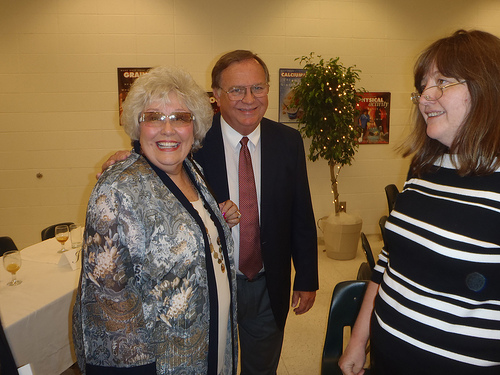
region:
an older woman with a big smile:
[82, 69, 249, 374]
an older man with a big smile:
[201, 46, 323, 373]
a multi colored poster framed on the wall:
[113, 62, 157, 127]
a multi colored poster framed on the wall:
[200, 90, 226, 119]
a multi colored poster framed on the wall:
[277, 69, 325, 124]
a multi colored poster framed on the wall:
[351, 88, 395, 142]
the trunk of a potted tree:
[327, 158, 342, 214]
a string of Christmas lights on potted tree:
[304, 53, 352, 213]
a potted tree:
[287, 51, 366, 256]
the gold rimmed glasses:
[408, 75, 468, 107]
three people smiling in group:
[108, 48, 470, 373]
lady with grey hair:
[121, 77, 192, 167]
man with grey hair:
[203, 52, 270, 135]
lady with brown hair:
[403, 37, 498, 166]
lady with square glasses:
[122, 83, 198, 172]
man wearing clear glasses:
[210, 46, 277, 126]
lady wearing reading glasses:
[414, 45, 476, 141]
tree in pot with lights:
[296, 65, 360, 257]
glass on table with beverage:
[0, 242, 32, 292]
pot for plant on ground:
[323, 203, 360, 255]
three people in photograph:
[38, 56, 485, 374]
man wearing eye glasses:
[216, 70, 283, 110]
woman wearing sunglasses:
[135, 88, 200, 152]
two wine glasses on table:
[1, 229, 109, 313]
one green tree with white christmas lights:
[294, 55, 384, 276]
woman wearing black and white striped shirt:
[402, 125, 498, 346]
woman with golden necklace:
[151, 190, 256, 287]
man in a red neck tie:
[221, 116, 314, 346]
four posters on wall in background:
[110, 63, 405, 171]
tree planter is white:
[317, 196, 390, 286]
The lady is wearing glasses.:
[118, 94, 220, 129]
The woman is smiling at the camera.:
[125, 87, 210, 190]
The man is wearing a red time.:
[219, 134, 287, 290]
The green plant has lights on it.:
[292, 66, 372, 246]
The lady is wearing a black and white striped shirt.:
[374, 153, 497, 373]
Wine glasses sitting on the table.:
[1, 224, 81, 280]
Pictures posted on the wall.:
[277, 71, 390, 168]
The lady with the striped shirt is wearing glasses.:
[393, 76, 483, 111]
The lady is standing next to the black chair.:
[312, 268, 378, 374]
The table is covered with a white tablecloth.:
[9, 265, 91, 345]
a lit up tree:
[286, 53, 362, 262]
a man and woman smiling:
[71, 48, 321, 374]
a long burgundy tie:
[234, 133, 263, 283]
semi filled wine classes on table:
[4, 222, 71, 287]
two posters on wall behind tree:
[277, 67, 392, 147]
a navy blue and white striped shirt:
[367, 148, 498, 374]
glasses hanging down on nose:
[409, 78, 470, 108]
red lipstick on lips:
[153, 138, 182, 153]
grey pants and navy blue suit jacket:
[191, 113, 318, 373]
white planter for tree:
[318, 210, 364, 264]